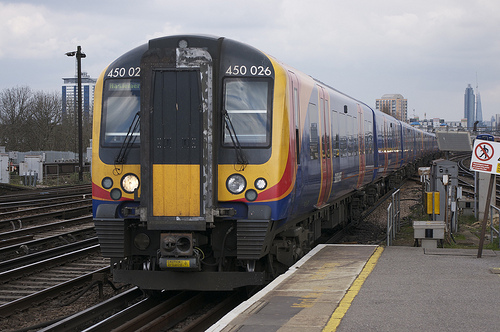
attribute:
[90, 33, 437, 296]
train — blue, red, yellow, transportatio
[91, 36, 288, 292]
train front — yellow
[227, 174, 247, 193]
headlight — out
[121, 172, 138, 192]
headlight — on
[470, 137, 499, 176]
sign — no crossing, white, red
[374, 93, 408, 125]
building — tall, multi story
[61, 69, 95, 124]
building — tall, multi story, blue, white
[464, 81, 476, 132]
building — tall, multi story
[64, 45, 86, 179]
electric pole — black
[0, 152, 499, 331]
tracks — silver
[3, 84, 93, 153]
trees — bare, brown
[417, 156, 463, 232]
electrical box — silver, gray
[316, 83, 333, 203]
doors — red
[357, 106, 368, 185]
doors — red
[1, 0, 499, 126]
sky — cloudy, stormy, dark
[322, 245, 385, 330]
stripe — yellow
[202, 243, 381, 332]
line — white